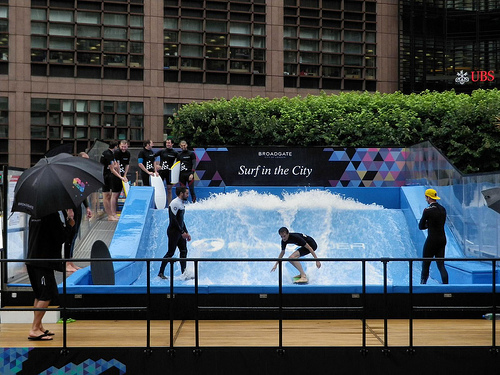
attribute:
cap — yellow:
[423, 184, 442, 201]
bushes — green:
[161, 85, 499, 179]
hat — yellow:
[423, 184, 443, 202]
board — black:
[79, 237, 120, 287]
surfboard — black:
[88, 239, 116, 286]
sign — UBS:
[453, 66, 499, 88]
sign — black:
[225, 146, 327, 183]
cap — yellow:
[426, 189, 439, 202]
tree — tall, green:
[167, 90, 498, 175]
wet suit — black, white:
[153, 173, 203, 278]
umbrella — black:
[11, 151, 106, 213]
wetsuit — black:
[268, 221, 379, 282]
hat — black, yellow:
[424, 187, 441, 201]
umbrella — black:
[7, 137, 103, 237]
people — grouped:
[102, 138, 197, 220]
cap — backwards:
[423, 187, 441, 200]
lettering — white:
[237, 151, 313, 179]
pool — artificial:
[53, 177, 497, 300]